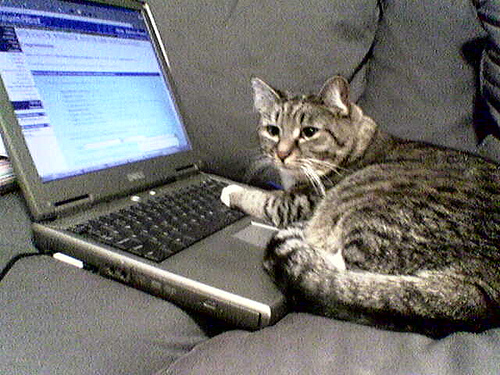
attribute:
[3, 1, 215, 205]
laptop — on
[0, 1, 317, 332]
laptop — silver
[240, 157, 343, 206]
whiskers — white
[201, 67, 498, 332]
cat's fur — brown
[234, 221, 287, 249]
touchpad — grey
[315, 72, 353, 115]
ear — grey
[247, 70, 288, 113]
ear — grey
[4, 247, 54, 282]
cord — black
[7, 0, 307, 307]
laptop — gray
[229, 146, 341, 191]
whiskers — long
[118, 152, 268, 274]
keyboard — black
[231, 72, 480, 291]
cat — laying down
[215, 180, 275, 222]
paws — grey, white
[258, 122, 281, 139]
eye — green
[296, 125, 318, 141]
eye — green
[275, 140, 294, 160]
nose — pink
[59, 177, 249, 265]
keys — dark gray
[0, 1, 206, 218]
monitor — laptop